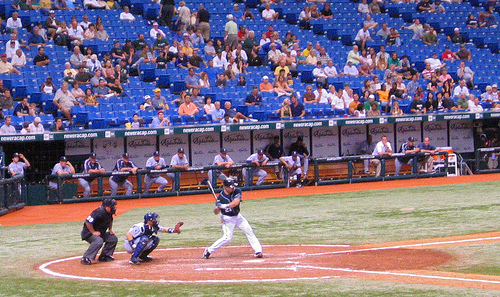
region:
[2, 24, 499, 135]
Baseball fans watching the game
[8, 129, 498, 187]
Baseball players standing on the side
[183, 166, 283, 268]
Player with bat in hand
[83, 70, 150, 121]
Empty chairs at the baseball game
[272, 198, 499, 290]
Baseball game field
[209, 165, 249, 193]
Baseball player's helmet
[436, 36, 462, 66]
Man wearing red shirt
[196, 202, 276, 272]
Player wearing white pants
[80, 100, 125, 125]
Blue colored chairs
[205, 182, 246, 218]
Player wearing a blue black shirt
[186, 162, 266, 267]
baseball player holding a bat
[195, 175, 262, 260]
baseball player wearing a blue shirt and white pants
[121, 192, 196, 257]
baseball player holding a baseball glove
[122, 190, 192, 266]
baseball player wearing a helmet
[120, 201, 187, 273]
baseball player squating to catch a ball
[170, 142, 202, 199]
baseball player wearing uniform shirt and blue hat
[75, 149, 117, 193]
baseball player wearing a hat and blue shirt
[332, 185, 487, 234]
green grass on a baseball field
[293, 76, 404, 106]
people watching a baseball game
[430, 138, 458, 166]
orange and white cooler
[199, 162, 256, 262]
this is a baseball player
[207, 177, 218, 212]
this is a bat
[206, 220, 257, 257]
the legs are apart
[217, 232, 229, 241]
the knee is bent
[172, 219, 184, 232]
this is a glove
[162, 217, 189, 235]
the hand is in front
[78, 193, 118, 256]
the umpire is squatting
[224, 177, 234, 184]
the helmet is black in color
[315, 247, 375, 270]
the pitch is brown in color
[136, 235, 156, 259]
he is wearing shin guards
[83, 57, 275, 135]
the chairs is blue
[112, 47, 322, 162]
the chairs is blue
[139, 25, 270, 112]
the chairs is blue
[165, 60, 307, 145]
the chairs is blue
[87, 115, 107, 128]
a blue seat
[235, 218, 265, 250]
a man's leg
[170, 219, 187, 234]
a catcher's brown glove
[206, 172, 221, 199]
a long baseball bat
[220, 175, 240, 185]
a dark colored baseball helmet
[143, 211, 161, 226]
a helmet and face mask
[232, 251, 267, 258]
a flat white base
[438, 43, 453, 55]
a male spectator in red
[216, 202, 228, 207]
a player's white glove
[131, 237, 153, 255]
protective leg pad